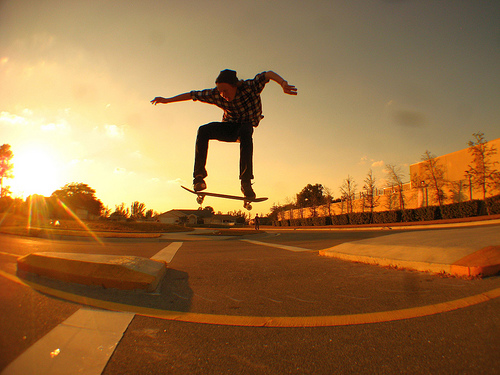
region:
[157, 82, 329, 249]
A man doing skating tricks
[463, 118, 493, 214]
A small green tree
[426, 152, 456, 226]
A small green tree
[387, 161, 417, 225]
A small green tree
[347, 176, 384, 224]
A small green tree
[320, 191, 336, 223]
A small green tree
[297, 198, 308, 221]
A small green tree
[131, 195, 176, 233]
A small green tree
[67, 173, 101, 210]
A small green tree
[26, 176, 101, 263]
sharp yellow sun rays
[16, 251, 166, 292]
Cement obstacle boy is jumping over.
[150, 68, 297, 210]
A boy is skateboarding in a parking lot.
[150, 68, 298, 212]
Boy on a skateboard is jumping.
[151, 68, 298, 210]
Boy in a plaid shirt and black pants.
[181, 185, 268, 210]
The skateboard the boy is riding.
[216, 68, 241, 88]
Black beanie hat on boys head.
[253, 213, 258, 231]
The boys friend watching way in the background.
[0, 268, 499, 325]
Yellow stripe running down the road.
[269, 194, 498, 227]
Row of square bushes lining a fence.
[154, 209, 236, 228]
White house in the background.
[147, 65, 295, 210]
skateboarder performing jumping trick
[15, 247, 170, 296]
flat concrete panel with horizontal angles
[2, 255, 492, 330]
white arc around edge of ground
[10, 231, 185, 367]
thick wide stripe toward center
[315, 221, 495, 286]
low ramp with paint on side borders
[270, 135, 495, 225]
row of thin trees and bushes against wall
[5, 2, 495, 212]
darkening sky with bright light at one end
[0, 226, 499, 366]
flat gray pavement in skate park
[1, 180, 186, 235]
low building, trees and landscaping on other side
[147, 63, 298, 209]
one arm extended and other twisted at elbow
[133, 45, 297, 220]
a skateboarder performing a stunt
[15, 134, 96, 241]
the late afternoon sun is shining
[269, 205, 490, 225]
neatly trimmed shrubs along the wall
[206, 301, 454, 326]
white bricks in the stree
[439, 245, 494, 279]
red paint on the edge of the curb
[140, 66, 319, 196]
a teenage wearing a plaid shirt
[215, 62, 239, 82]
a black knit cap on a head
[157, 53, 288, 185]
a teenager wearing blue jeans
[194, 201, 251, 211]
wheels underneath the skateboard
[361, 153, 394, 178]
white clouds in the sky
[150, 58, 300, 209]
skateboarder doing a trick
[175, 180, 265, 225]
skateboard being rode in air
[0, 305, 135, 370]
white line painted on ground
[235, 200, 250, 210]
wheels on the skateboard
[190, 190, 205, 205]
front wheels on skateboard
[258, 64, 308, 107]
left arm on skateboarder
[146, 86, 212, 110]
right arm of skateboarder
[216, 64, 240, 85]
black hat on guy's head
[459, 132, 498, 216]
bare tree in the background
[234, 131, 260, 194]
left leg of the skateboarder